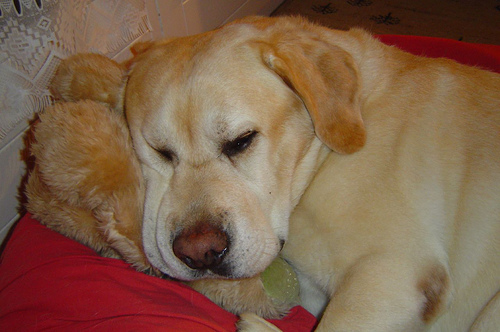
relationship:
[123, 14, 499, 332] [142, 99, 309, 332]
animal looks sleepy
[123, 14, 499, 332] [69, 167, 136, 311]
animal laying on a stuffed animal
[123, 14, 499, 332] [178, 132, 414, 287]
animal pale tan in collor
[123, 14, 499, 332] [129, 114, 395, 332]
animal face squished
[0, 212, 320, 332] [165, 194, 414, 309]
cushion under dog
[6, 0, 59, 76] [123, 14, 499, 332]
design behind animal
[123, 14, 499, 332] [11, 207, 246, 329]
animal sleeping on bed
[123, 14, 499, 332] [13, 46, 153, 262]
animal sleeping on stuffed animal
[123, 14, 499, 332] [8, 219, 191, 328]
animal sleeping on bed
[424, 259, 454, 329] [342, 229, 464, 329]
patch on elbow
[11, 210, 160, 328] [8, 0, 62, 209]
bed leaning against wall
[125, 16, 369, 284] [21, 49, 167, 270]
head resting on stuffed animal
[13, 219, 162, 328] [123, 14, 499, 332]
cushion under animal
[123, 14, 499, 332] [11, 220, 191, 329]
animal laying on a cushion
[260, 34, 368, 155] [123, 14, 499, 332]
dog's ear of animal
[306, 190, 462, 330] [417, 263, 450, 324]
dog's leg has patch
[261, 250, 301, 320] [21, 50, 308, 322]
foot of stuffed animal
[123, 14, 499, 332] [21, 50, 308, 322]
animal sleeping by stuffed animal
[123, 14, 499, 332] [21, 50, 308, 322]
animal laying on stuffed animal